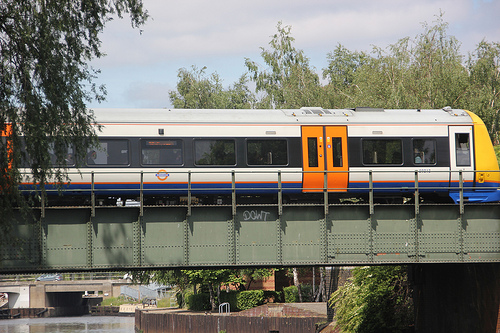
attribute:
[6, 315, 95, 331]
river — small bit 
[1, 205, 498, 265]
bridges — many 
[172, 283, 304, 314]
bushes — green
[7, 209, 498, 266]
bridge — green , steel 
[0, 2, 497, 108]
sky — blue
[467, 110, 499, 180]
paint — yellow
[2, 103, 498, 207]
train — very colorful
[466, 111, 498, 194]
end — yellow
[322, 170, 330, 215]
rail post — safety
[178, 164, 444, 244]
rail post — safety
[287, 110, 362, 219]
doors — orange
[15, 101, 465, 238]
train — commuter